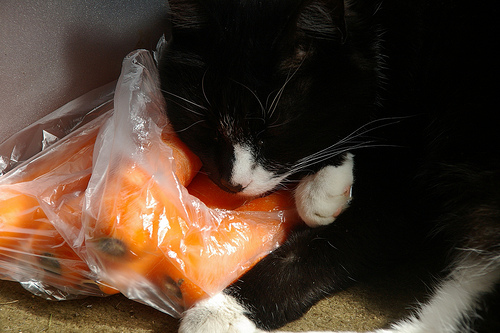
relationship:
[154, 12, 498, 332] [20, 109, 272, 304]
cat sleeping carrots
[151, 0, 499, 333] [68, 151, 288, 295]
cat lying carrots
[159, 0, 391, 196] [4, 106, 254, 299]
head resting on carrots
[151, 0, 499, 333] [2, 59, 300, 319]
cat laying on carrots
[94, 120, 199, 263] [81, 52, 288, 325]
carrot seen through a bag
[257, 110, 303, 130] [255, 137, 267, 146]
eye have tears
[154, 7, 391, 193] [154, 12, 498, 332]
head of a cat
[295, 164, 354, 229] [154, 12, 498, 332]
paw of a cat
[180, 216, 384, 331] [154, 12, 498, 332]
leg of a cat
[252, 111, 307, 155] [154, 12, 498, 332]
eye of a cat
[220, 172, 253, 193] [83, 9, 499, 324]
nose of a cat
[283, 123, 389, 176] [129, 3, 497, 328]
whiskers of a cat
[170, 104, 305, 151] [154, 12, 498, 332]
eyes of a cat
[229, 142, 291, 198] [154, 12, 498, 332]
white on cat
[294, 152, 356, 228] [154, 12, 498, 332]
white on cat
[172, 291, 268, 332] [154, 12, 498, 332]
white on cat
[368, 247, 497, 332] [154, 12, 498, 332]
white on cat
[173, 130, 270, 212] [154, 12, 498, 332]
nose of cat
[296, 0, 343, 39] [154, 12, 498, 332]
cat ear of cat